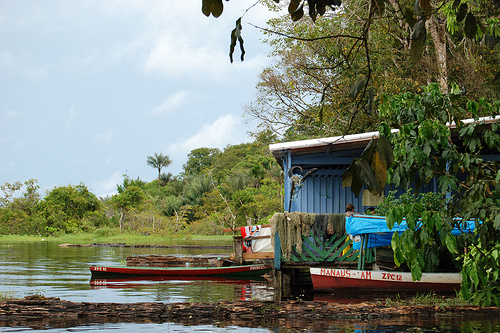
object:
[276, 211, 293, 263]
net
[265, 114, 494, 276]
house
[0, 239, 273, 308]
river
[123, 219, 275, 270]
dock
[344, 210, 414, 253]
clothes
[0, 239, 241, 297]
water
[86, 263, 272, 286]
boat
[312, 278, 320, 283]
paint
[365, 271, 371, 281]
letters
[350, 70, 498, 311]
tree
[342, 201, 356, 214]
person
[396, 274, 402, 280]
number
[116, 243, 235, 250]
shoreline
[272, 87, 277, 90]
leaves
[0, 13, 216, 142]
sky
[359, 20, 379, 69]
stem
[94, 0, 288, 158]
cloud